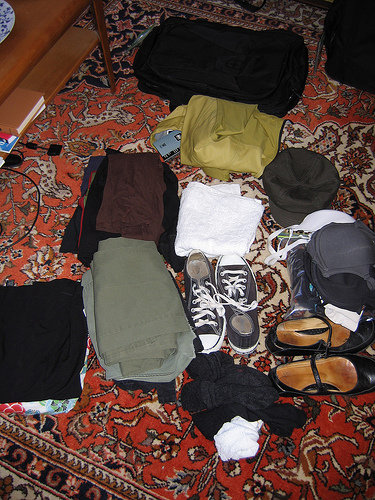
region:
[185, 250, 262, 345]
a pair of tennis shoes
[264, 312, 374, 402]
a pair of dress shoes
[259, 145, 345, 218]
a gray hat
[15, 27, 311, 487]
a large oriental rug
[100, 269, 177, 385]
a folded pair of green pants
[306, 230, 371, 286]
a dark blue bra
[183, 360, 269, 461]
a pile of socks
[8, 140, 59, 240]
a charger's black cord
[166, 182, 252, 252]
a folded white towel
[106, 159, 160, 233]
a folded dark red shirt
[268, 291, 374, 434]
a pair of black shoes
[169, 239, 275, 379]
a pair of converse-style sneakers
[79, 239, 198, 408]
multiple pairs of folded pants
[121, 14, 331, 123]
a black duffel bag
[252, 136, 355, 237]
a gray-green hat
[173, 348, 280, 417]
a pair of dark gray socks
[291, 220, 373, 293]
a gray folded bra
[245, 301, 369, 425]
pair of women's flats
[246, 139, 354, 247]
a woman's hat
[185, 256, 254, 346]
a pair of dark grey sneakers with white shoelaces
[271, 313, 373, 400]
a pair of black mary janes with brown inner soles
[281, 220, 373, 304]
three bras in white grey and black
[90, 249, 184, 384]
a stack of khaki pants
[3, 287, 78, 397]
a black folded item of clothing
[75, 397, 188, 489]
a red white and brown ornate rug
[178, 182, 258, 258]
a folded white shirt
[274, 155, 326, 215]
a grey newsboy cap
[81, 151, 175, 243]
a stack of folded multi colored shirts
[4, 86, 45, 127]
a brown book on a wooden ledge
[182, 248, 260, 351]
Gray and white sneakers among other clothes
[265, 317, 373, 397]
Black Mary Jane shoes under the bras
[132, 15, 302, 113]
An empty black piece of luggage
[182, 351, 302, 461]
A small pile of socks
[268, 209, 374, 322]
A small pile of neutral-colored bras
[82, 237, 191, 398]
A stack of pants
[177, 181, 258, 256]
A white towel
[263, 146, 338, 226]
A dark brown cap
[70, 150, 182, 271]
A pile of shorts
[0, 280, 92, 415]
A pile of shirts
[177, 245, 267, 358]
blue and white canvas shies.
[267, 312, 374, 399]
black striped women's shoes.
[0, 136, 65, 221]
A black power cord for a cell phone.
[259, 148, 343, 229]
A dark gray hat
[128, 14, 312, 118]
A black travel bag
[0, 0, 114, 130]
A brown wooden coffee table.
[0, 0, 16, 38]
A blue and white ceramic dish.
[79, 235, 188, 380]
A folded pair of beige pants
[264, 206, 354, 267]
A white woman's bra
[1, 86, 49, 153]
A stack of three books.